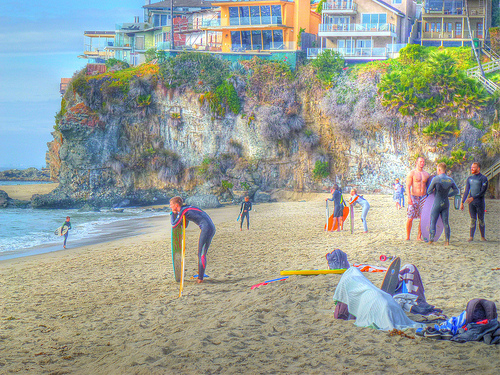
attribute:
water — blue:
[0, 187, 138, 267]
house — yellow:
[199, 0, 320, 70]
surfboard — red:
[325, 206, 350, 232]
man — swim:
[399, 149, 438, 249]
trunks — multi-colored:
[404, 190, 430, 220]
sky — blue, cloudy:
[2, 7, 78, 74]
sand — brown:
[122, 303, 279, 368]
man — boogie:
[416, 160, 486, 255]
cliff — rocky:
[31, 63, 498, 199]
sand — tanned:
[18, 286, 139, 358]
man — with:
[169, 195, 214, 283]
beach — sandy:
[0, 188, 499, 372]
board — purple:
[418, 189, 450, 248]